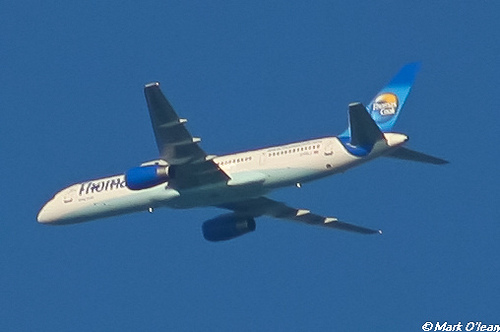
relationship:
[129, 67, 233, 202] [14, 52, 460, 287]
wing attached to plane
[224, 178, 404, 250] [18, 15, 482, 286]
wing attached to plane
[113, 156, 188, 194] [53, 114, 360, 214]
engine attached to plane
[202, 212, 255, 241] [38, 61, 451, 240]
engine attached to plane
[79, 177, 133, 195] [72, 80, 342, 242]
words on plane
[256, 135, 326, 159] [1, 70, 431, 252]
window on plane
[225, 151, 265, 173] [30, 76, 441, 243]
windows on plane